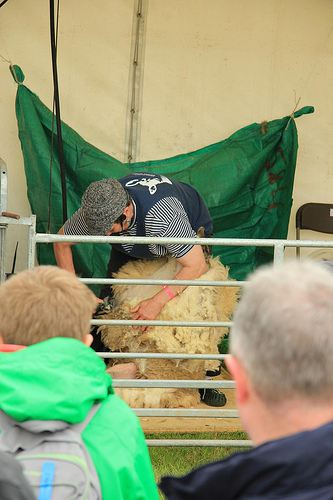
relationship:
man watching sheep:
[237, 265, 324, 494] [99, 257, 226, 355]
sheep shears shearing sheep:
[96, 292, 119, 313] [96, 257, 235, 405]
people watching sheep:
[0, 253, 305, 395] [96, 257, 235, 405]